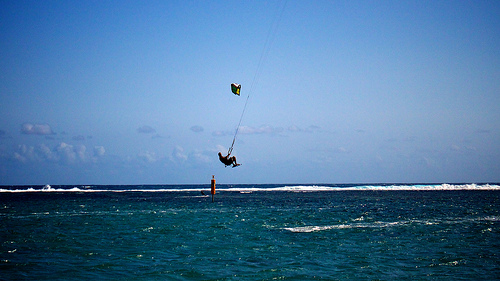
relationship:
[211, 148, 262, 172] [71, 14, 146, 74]
man in sky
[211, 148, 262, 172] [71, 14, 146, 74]
man near sky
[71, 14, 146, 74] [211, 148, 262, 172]
sky above man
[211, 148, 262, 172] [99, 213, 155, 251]
man above ocean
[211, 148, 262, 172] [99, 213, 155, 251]
man in ocean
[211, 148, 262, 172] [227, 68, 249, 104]
man with kite